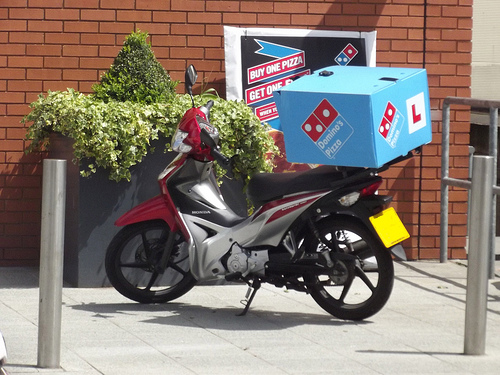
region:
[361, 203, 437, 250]
yellow sign at back of bike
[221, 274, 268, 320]
bike's frame on the ground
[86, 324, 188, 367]
lines on the ground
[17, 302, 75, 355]
large silver pole on the sidewalk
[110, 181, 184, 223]
red color on the bike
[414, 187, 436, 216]
dark red bricks on the wall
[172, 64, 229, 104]
black mirrors on bike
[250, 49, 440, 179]
large blue pizza box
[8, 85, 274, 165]
green leaves in enclosure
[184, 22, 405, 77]
black and white poster on the wall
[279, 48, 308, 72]
Pizza written on a sign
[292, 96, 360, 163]
Domino's Pizza written on a box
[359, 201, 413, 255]
Yellow license plate on a scooter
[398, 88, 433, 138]
L written on the back of a box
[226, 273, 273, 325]
kick stand of a scooter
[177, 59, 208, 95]
Right mirror of a scooter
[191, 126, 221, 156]
Left mirror of a scooter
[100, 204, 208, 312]
front wheel of a scooter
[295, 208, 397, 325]
Rear wheel of a scooter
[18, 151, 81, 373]
metal pole on a sidewalk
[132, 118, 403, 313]
A motorcycle on the sidewalk.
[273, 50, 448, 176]
A dominoes box by the bike.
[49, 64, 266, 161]
Green plant on the stand.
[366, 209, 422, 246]
The bike has a yellow tag.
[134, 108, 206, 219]
The bike is red and white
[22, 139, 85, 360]
A silver pole on the sidewalk.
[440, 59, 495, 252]
Railing on the side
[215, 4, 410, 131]
A dominoes sign on the wall.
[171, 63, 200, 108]
Side mirror on the bike.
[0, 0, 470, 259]
the wall of the building is made of bricks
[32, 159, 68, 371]
the pole in the ground is made of metal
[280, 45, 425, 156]
blue domino's delivery box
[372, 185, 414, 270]
yellow license plate on bike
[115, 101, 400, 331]
red and white motorcycle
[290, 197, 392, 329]
back wheel of bike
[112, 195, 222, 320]
front wheel of bike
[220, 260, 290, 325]
kickstand of red bike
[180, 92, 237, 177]
handlebars of red bike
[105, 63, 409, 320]
the motorcycle is red and silver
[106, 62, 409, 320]
the yellow license plate on the motorcycle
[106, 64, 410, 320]
the motorcycle is parked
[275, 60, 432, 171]
the box is blue, red and white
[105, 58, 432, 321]
the box on the motorcycle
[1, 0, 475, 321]
the motorcycle parked next to the red brick wall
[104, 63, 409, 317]
the motorcycle held up by the kickstand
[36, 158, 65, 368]
the post is silver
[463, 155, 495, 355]
the post is silver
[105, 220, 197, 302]
the tire is black